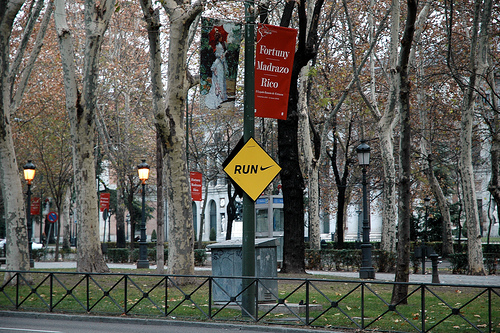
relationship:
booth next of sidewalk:
[257, 197, 282, 236] [447, 269, 492, 283]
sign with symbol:
[211, 130, 289, 210] [259, 162, 277, 172]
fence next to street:
[1, 269, 498, 331] [47, 310, 158, 329]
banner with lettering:
[253, 14, 299, 121] [255, 60, 291, 74]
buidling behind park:
[0, 73, 500, 247] [5, 264, 490, 326]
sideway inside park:
[308, 270, 496, 286] [0, 248, 500, 331]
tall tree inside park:
[139, 0, 209, 289] [1, 3, 499, 332]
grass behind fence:
[308, 271, 397, 320] [1, 269, 498, 331]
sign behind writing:
[224, 132, 284, 201] [229, 160, 258, 176]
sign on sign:
[223, 133, 282, 204] [215, 128, 287, 209]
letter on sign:
[232, 164, 242, 174] [224, 138, 283, 202]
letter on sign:
[240, 160, 249, 176] [224, 138, 283, 202]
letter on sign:
[251, 162, 258, 174] [211, 130, 289, 210]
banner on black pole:
[253, 14, 299, 121] [241, 0, 256, 322]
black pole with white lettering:
[241, 0, 256, 322] [253, 37, 290, 99]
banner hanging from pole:
[244, 14, 304, 131] [16, 169, 40, 271]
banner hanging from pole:
[244, 14, 304, 131] [128, 168, 151, 252]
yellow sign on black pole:
[221, 136, 281, 201] [241, 0, 256, 322]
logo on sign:
[257, 162, 274, 171] [221, 135, 281, 205]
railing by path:
[0, 268, 500, 331] [1, 315, 307, 331]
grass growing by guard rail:
[308, 271, 397, 320] [0, 269, 499, 330]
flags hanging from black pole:
[194, 15, 289, 118] [241, 0, 256, 322]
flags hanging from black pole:
[188, 166, 203, 203] [241, 0, 256, 322]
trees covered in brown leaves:
[1, 2, 497, 284] [4, 0, 496, 202]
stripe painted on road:
[0, 326, 65, 331] [0, 310, 303, 331]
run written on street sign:
[236, 161, 260, 173] [209, 135, 290, 209]